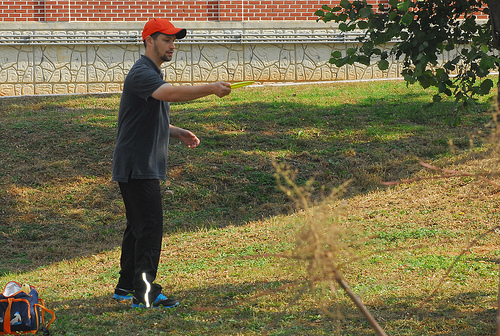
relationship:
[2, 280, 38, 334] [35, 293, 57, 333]
bag has orange straps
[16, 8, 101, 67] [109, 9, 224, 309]
wall behind man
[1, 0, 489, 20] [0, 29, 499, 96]
red brick over fake stone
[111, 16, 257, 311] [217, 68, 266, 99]
man throwing frisbee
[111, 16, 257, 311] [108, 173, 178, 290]
man in pants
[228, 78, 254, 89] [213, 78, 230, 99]
frisbee in hand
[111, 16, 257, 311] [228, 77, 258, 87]
man throwing frisbee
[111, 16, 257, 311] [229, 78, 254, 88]
man playing frisbee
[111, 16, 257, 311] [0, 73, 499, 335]
man in ground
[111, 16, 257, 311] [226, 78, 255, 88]
man playing frisbee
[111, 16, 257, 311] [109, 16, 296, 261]
man playing playing frisbee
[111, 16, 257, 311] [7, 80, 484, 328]
man standing grass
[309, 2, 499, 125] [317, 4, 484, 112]
leaves on tree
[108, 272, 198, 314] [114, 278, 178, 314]
shoes on feet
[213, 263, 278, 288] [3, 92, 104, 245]
dirt in grass